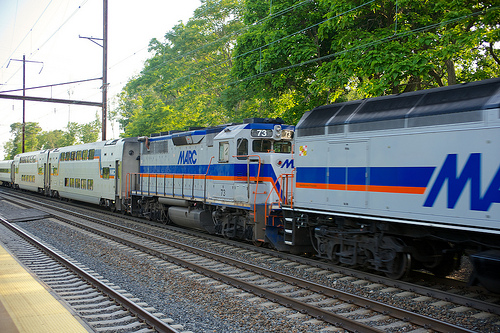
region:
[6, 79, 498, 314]
a long train on the track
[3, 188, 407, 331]
an empty train track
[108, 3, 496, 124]
green leafy trees next to the train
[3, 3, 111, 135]
some power lines connected by poles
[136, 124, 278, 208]
a colorful train engine pulling the train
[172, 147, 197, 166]
a name written on the train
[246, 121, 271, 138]
the number of the engine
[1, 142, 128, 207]
the mostly white passenger cars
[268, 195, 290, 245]
the steps on the engine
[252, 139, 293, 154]
the window for the conductor to see out of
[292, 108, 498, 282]
a gray and orange and blue train car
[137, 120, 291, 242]
a gray and orange and blue train car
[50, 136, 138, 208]
a gray and orange and blue train car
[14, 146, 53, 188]
a gray and orange and blue train car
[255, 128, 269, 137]
the number 73 on a train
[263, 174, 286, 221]
a bright orange handle to stairs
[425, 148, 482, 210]
a large letter M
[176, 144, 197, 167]
the marc word on a train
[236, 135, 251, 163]
the small window of a train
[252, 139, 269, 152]
the small window of a train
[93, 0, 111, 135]
power line pole near tracks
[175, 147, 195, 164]
company sponsored the train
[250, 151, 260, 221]
handle for operator to climb aboard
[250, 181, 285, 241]
stairs to board the train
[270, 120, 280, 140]
head light for night travel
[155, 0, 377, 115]
tree landscape near the tracks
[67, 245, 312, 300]
unused train tracks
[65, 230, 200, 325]
rocky gravel landscape near tracks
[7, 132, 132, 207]
passenger carts on train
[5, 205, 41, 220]
walk way path for operator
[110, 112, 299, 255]
a train engine.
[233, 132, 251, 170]
a window on a train.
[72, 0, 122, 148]
a tall power pole.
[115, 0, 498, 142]
lots of green trees lining a train track.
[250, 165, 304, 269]
a ladder on a train engine.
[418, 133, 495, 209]
writing on the side of a train.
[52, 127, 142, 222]
a white train car on tracks.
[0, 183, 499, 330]
train tracks on the ground.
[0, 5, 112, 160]
a tall wooden power pole.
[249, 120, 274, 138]
the number 73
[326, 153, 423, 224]
blue and orange line on train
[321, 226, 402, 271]
bottom part of the train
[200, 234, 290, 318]
tracks next to train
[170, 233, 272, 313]
brown tracks on the ground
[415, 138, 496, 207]
the letter M on train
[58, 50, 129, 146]
long pole next to train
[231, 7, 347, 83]
tree next to train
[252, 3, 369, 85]
green leaves on the tree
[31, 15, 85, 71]
light sky above the land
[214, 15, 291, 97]
wires above train